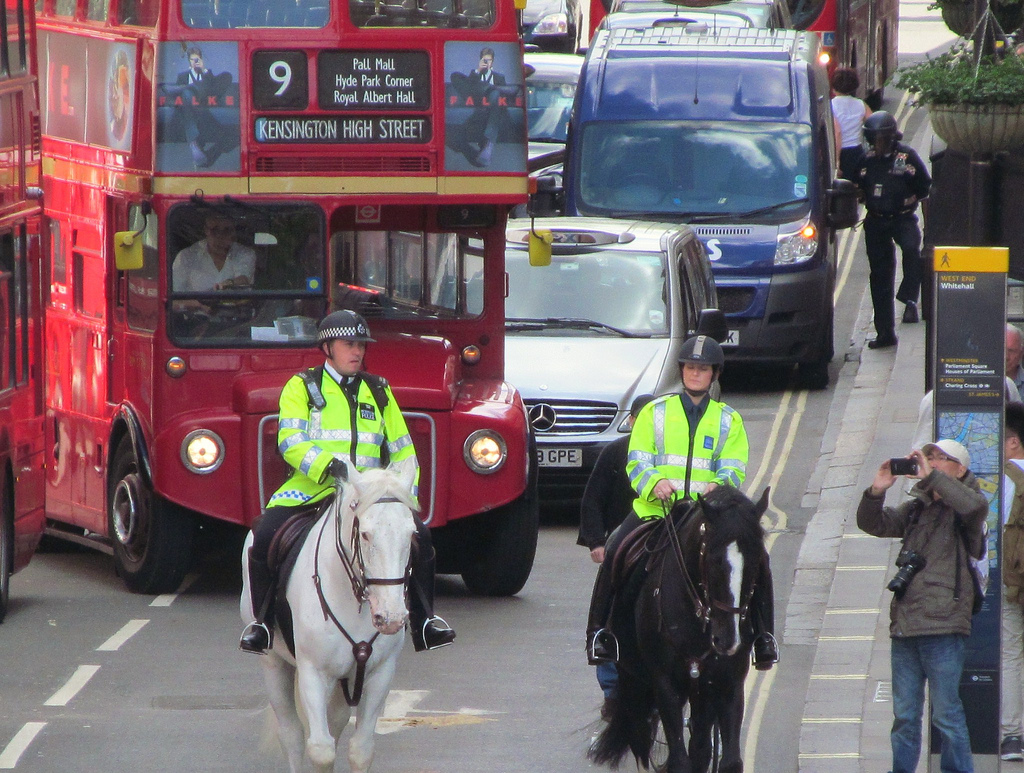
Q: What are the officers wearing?
A: Reflective jackets.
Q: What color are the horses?
A: One is black, One is White.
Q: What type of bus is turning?
A: A double decker.